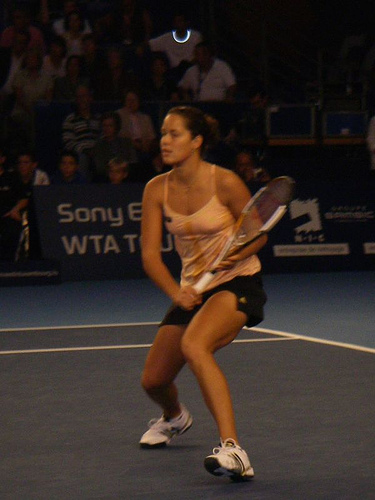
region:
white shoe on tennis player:
[192, 435, 264, 483]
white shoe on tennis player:
[140, 407, 192, 464]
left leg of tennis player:
[178, 328, 248, 438]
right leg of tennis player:
[140, 361, 187, 418]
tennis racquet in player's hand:
[222, 178, 285, 283]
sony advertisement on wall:
[56, 199, 121, 226]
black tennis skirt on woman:
[152, 281, 266, 316]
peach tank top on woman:
[155, 169, 249, 278]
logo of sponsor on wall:
[267, 197, 348, 259]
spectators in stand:
[40, 147, 136, 191]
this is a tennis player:
[125, 100, 266, 442]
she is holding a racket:
[195, 246, 239, 288]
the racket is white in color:
[262, 204, 287, 235]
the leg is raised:
[195, 442, 251, 485]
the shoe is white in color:
[223, 449, 242, 467]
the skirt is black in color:
[240, 281, 261, 305]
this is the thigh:
[200, 311, 224, 345]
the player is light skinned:
[207, 311, 229, 326]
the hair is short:
[200, 118, 217, 130]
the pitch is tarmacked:
[21, 361, 111, 469]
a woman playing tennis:
[109, 45, 232, 470]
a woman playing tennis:
[156, 198, 261, 469]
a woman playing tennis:
[150, 95, 311, 476]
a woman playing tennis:
[173, 240, 224, 467]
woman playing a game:
[101, 112, 301, 326]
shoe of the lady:
[194, 425, 262, 489]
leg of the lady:
[189, 373, 250, 424]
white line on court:
[52, 330, 106, 378]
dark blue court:
[265, 394, 312, 450]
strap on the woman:
[199, 154, 227, 193]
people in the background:
[45, 76, 154, 190]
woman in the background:
[89, 108, 137, 160]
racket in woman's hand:
[225, 167, 301, 260]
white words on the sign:
[68, 199, 128, 259]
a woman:
[111, 118, 273, 439]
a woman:
[90, 104, 238, 344]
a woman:
[94, 104, 363, 497]